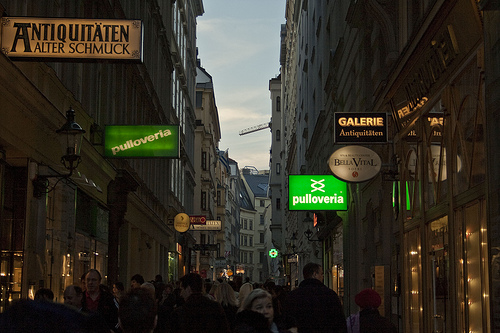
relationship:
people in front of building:
[0, 262, 403, 332] [347, 2, 497, 330]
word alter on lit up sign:
[32, 38, 66, 55] [0, 15, 145, 65]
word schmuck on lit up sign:
[66, 40, 134, 56] [0, 15, 145, 65]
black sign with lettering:
[333, 111, 389, 145] [336, 116, 384, 137]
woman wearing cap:
[342, 279, 396, 331] [355, 288, 382, 309]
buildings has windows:
[239, 167, 268, 287] [249, 217, 253, 230]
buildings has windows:
[239, 167, 268, 287] [248, 249, 252, 260]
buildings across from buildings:
[268, 1, 498, 329] [1, 2, 263, 331]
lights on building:
[458, 220, 488, 330] [347, 2, 497, 330]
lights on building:
[406, 237, 421, 331] [347, 2, 497, 330]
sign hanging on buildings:
[326, 144, 386, 184] [268, 75, 285, 288]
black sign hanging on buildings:
[334, 111, 386, 144] [268, 75, 285, 288]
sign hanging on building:
[101, 120, 184, 160] [7, 0, 197, 332]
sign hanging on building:
[172, 207, 190, 232] [7, 0, 197, 332]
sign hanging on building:
[1, 14, 146, 61] [7, 0, 197, 332]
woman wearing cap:
[345, 288, 391, 332] [351, 283, 384, 309]